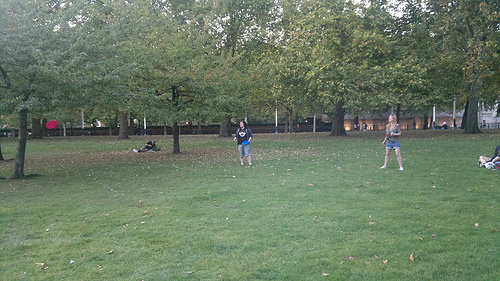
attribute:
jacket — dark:
[219, 126, 254, 144]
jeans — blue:
[384, 139, 400, 148]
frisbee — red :
[39, 110, 64, 135]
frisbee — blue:
[240, 139, 250, 147]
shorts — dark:
[209, 137, 260, 151]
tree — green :
[111, 22, 238, 158]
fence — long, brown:
[7, 121, 427, 133]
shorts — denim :
[380, 128, 410, 150]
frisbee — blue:
[239, 137, 251, 147]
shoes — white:
[375, 161, 407, 172]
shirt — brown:
[383, 128, 401, 139]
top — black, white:
[234, 123, 253, 141]